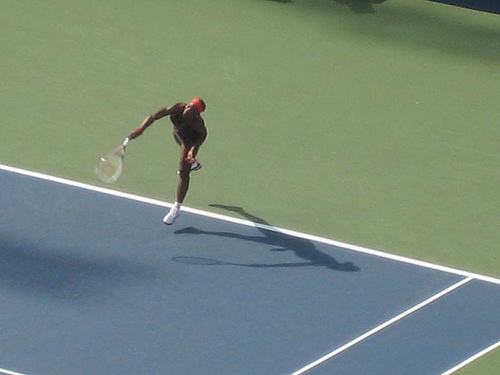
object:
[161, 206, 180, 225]
shoe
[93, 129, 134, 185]
racket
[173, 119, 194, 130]
shirt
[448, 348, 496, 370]
white line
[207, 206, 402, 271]
white line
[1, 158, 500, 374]
tennis court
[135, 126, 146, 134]
wrist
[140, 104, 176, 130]
arm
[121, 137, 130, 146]
white handle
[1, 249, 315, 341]
court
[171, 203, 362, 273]
shadow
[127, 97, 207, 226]
man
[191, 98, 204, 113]
headband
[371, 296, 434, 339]
line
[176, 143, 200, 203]
left leg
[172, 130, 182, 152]
right leg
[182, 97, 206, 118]
head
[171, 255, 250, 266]
racket shadow